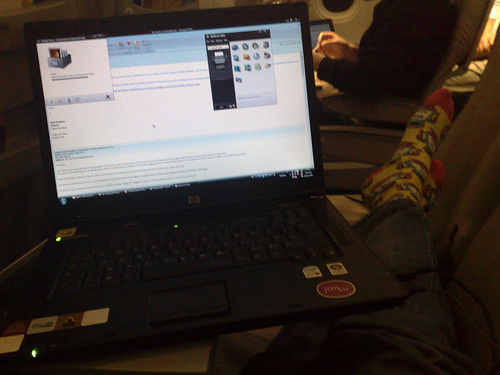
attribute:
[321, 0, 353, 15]
window — round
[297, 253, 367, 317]
sticker — oval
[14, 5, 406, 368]
laptop — powered up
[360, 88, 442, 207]
socks — red 